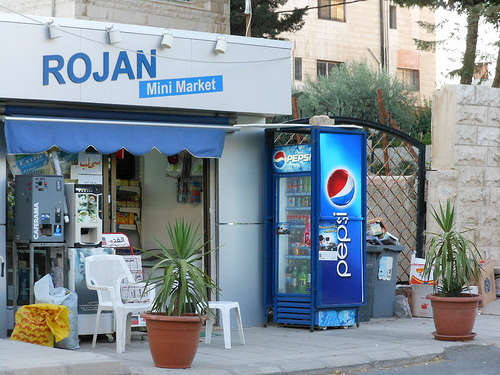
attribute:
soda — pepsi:
[290, 185, 302, 195]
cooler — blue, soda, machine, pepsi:
[272, 122, 370, 325]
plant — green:
[150, 222, 210, 315]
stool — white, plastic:
[92, 247, 143, 341]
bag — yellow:
[15, 301, 72, 338]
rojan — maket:
[35, 48, 157, 81]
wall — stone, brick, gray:
[321, 34, 352, 46]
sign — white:
[160, 20, 285, 102]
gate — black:
[366, 131, 415, 173]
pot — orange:
[143, 325, 200, 366]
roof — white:
[180, 19, 206, 35]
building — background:
[392, 1, 463, 68]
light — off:
[201, 27, 250, 60]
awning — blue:
[109, 129, 198, 162]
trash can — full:
[370, 222, 399, 317]